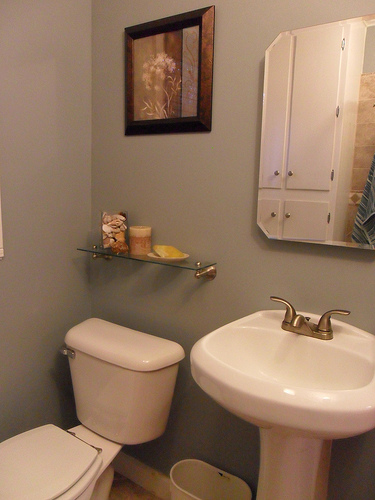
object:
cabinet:
[255, 17, 370, 246]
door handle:
[288, 171, 293, 176]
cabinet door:
[258, 35, 293, 190]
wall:
[93, 1, 375, 500]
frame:
[123, 3, 215, 138]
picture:
[131, 23, 201, 122]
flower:
[167, 60, 176, 71]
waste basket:
[168, 458, 254, 500]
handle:
[59, 347, 74, 358]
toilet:
[0, 316, 186, 500]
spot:
[218, 471, 224, 476]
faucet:
[316, 309, 351, 341]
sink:
[189, 308, 374, 442]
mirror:
[333, 19, 373, 248]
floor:
[105, 469, 162, 499]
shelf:
[76, 245, 216, 275]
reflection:
[343, 73, 375, 246]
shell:
[102, 224, 112, 234]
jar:
[100, 210, 130, 254]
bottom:
[256, 355, 344, 392]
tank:
[61, 317, 186, 445]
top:
[63, 316, 185, 374]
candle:
[128, 225, 153, 255]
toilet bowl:
[0, 430, 101, 500]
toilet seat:
[54, 456, 104, 500]